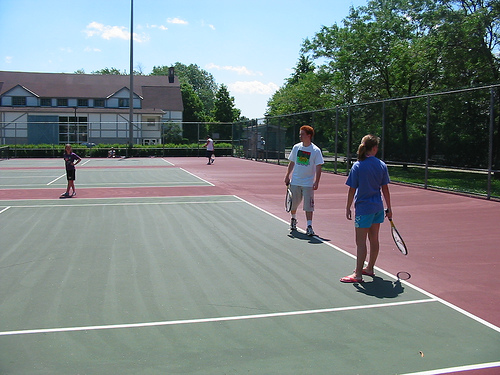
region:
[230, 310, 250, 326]
MARKING ON THE GROUND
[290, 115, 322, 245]
THIS IS A PERSON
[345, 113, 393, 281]
THIS IS A PERSON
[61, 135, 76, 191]
THIS IS A PERSON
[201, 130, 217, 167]
THIS IS A PERSON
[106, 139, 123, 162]
THIS IS A PERSON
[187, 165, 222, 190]
The court is green and red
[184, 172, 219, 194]
The tennis court is red and green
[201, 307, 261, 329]
Line on a court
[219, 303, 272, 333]
White line on a court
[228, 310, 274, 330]
White line on a tennis court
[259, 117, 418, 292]
The people are playing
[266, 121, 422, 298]
The people are playing tennis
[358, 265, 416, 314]
Shadow of a girl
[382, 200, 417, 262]
Racket in a hand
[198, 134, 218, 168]
Person in the background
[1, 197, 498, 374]
a green marked tennis court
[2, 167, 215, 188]
a green marked tennis court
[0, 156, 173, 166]
a green marked tennis court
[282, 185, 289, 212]
a black tennis racket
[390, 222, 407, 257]
a black tennis racketa black tennis racket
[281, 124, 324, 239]
a male tennis player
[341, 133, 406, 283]
a female tennis player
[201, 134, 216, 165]
a male tennis player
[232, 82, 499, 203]
a chain link fence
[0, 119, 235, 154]
a chain link fence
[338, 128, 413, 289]
woman holding tennis racket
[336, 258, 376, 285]
pair of pink flip flops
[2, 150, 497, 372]
maroon and green tennis court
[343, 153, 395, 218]
blue short sleeve shirt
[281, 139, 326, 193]
white short sleeve shirt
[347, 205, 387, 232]
pair of teal and white shorts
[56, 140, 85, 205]
person walking on tennis court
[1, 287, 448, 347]
white line on tennis court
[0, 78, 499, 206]
tall metal fence surrounding tennis court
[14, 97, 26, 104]
glass window on building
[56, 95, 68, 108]
glass window on building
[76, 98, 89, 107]
glass window on building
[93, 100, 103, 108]
glass window on building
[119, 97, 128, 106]
glass window on building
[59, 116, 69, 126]
glass window on building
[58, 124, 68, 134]
glass window on building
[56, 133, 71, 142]
glass window on building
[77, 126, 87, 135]
glass window on building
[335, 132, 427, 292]
girl wearing purble shirt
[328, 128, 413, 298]
girl wearing blue shorts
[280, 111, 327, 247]
man wearing a t shirt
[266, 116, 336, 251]
man wearing kaki shorts